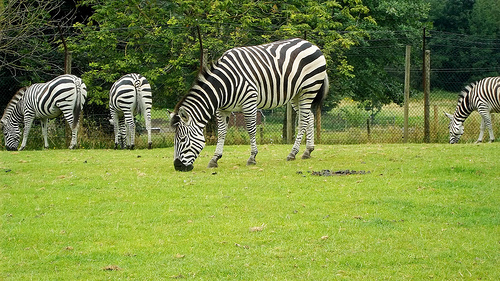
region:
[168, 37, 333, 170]
a zebra is standing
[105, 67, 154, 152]
a zebra is standing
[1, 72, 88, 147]
a zebra is standing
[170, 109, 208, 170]
head of a zebra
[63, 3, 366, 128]
a tree with light green leaves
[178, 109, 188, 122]
ear of a zebra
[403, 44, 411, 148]
a thin wooden post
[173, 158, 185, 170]
nose of a zebra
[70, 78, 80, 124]
tail of a zebra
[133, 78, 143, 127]
tail of a zebra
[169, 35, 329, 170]
A zebra eating grass.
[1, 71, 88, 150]
A zebra eating grass.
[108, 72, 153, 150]
Rear end of a zebra.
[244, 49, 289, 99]
Striped fur of a zebra.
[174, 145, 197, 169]
Snout of a zebra.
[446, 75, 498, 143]
A zebra eating grass.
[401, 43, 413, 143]
Wooden pole holding up wire fence.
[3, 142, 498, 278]
Bright green grass in a zebra's enclosure.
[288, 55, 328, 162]
Rear legs of a zebra.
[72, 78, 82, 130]
A zebra's dangling tail.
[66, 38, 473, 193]
zebras in a field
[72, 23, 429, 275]
zebras standing in a field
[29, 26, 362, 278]
zebras eatting in a field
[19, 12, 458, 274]
zebras eatting grass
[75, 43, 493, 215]
zebras eatting green grass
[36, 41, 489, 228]
zebras with their head down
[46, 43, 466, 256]
zebras that are fenced in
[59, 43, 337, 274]
a field of zebras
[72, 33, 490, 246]
an area of zebras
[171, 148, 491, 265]
a field of green grass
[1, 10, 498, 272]
Zebra's standing in the zoo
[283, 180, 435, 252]
Green color grass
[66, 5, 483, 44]
Lot of trees with green leaves and branches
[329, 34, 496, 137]
Concrete pole with fencing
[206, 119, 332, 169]
Legs of the zebra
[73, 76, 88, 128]
Tail of the zebra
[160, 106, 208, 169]
Head of the zebra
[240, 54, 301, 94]
Black and white color stripes of the zebra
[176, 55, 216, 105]
Black and white color manes of the zebra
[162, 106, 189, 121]
Large upright ears of the zebra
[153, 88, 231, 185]
the head of a zebra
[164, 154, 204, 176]
the mouth of a zebra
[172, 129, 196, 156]
the eye of a zebra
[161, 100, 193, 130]
the ear of a zebra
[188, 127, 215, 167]
the jaw of a zebra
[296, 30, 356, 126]
the tail of a zebra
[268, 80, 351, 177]
the back legs of a zebra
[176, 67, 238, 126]
the neck of a zebra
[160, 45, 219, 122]
the main of a zebra